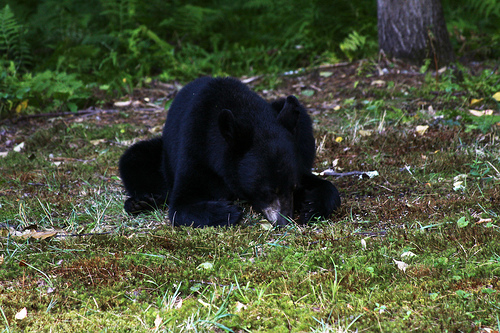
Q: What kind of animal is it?
A: Bear.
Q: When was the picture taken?
A: Daytime.